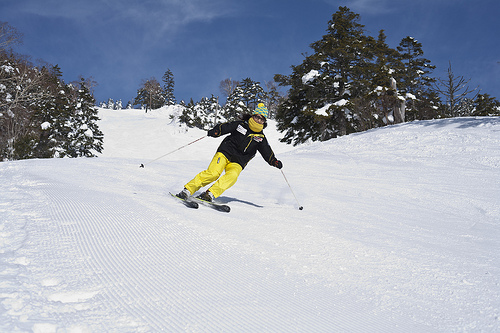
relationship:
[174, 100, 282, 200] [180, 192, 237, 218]
skier in skis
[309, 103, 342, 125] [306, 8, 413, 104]
snow on tree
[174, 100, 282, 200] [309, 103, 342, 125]
skier in snow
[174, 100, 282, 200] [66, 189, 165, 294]
skier on ground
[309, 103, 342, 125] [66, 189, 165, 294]
snow on ground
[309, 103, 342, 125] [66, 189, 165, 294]
snow in ground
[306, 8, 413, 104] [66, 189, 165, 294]
tree in ground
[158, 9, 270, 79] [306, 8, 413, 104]
sky above tree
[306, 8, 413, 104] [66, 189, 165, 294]
tree on ground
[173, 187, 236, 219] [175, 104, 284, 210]
skis on downhill skier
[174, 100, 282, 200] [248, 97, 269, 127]
skier wearing cap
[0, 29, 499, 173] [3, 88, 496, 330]
trees in snow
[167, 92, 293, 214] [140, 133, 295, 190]
skier using ski poles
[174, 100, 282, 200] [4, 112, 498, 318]
skier skiing down mountain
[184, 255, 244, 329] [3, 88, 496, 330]
lines in snow